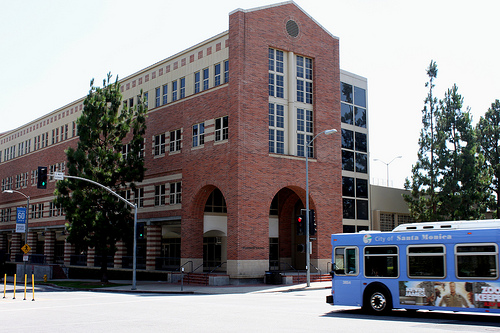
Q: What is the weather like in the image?
A: It is cloudy.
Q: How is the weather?
A: It is cloudy.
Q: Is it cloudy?
A: Yes, it is cloudy.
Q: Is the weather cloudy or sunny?
A: It is cloudy.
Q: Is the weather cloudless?
A: No, it is cloudy.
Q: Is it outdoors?
A: Yes, it is outdoors.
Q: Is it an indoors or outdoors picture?
A: It is outdoors.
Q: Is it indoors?
A: No, it is outdoors.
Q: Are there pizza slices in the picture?
A: No, there are no pizza slices.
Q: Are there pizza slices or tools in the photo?
A: No, there are no pizza slices or tools.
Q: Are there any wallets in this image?
A: No, there are no wallets.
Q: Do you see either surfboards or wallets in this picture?
A: No, there are no wallets or surfboards.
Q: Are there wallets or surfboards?
A: No, there are no wallets or surfboards.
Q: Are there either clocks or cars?
A: No, there are no cars or clocks.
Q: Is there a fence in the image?
A: No, there are no fences.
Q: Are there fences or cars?
A: No, there are no fences or cars.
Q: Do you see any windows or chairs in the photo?
A: Yes, there is a window.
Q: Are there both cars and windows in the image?
A: No, there is a window but no cars.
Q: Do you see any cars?
A: No, there are no cars.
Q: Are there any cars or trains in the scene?
A: No, there are no cars or trains.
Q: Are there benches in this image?
A: No, there are no benches.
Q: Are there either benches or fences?
A: No, there are no benches or fences.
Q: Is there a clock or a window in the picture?
A: Yes, there is a window.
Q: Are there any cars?
A: No, there are no cars.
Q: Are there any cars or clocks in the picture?
A: No, there are no cars or clocks.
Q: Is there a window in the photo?
A: Yes, there is a window.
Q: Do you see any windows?
A: Yes, there is a window.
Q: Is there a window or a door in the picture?
A: Yes, there is a window.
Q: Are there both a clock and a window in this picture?
A: No, there is a window but no clocks.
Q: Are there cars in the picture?
A: No, there are no cars.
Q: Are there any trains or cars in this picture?
A: No, there are no cars or trains.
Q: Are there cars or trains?
A: No, there are no cars or trains.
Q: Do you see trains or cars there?
A: No, there are no cars or trains.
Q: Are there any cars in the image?
A: No, there are no cars.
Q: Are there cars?
A: No, there are no cars.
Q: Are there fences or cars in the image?
A: No, there are no cars or fences.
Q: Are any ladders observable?
A: No, there are no ladders.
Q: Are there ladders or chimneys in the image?
A: No, there are no ladders or chimneys.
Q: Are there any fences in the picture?
A: No, there are no fences.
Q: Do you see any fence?
A: No, there are no fences.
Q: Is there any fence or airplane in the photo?
A: No, there are no fences or airplanes.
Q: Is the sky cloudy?
A: Yes, the sky is cloudy.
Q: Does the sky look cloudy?
A: Yes, the sky is cloudy.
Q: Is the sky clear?
A: No, the sky is cloudy.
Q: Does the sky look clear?
A: No, the sky is cloudy.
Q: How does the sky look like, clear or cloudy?
A: The sky is cloudy.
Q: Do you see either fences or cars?
A: No, there are no cars or fences.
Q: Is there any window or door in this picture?
A: Yes, there is a window.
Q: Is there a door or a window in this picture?
A: Yes, there is a window.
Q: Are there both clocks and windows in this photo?
A: No, there is a window but no clocks.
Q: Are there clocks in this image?
A: No, there are no clocks.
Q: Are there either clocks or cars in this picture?
A: No, there are no clocks or cars.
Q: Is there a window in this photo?
A: Yes, there is a window.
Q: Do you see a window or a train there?
A: Yes, there is a window.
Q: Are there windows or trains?
A: Yes, there is a window.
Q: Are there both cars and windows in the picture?
A: No, there is a window but no cars.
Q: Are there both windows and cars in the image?
A: No, there is a window but no cars.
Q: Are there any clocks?
A: No, there are no clocks.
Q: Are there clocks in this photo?
A: No, there are no clocks.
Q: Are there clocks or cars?
A: No, there are no clocks or cars.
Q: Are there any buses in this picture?
A: Yes, there is a bus.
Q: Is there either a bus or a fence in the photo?
A: Yes, there is a bus.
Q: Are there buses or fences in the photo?
A: Yes, there is a bus.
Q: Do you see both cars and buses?
A: No, there is a bus but no cars.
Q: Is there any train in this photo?
A: No, there are no trains.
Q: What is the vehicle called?
A: The vehicle is a bus.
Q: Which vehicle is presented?
A: The vehicle is a bus.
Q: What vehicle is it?
A: The vehicle is a bus.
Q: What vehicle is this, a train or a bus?
A: This is a bus.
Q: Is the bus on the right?
A: Yes, the bus is on the right of the image.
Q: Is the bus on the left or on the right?
A: The bus is on the right of the image.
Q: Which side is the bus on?
A: The bus is on the right of the image.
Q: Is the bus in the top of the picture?
A: No, the bus is in the bottom of the image.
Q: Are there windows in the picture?
A: Yes, there is a window.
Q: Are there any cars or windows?
A: Yes, there is a window.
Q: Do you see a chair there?
A: No, there are no chairs.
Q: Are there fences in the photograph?
A: No, there are no fences.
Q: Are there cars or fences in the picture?
A: No, there are no fences or cars.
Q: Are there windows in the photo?
A: Yes, there is a window.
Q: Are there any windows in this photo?
A: Yes, there is a window.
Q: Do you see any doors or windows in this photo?
A: Yes, there is a window.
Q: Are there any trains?
A: No, there are no trains.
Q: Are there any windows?
A: Yes, there is a window.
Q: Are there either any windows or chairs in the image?
A: Yes, there is a window.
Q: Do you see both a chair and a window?
A: No, there is a window but no chairs.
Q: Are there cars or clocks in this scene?
A: No, there are no cars or clocks.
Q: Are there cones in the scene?
A: No, there are no cones.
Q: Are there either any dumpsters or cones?
A: No, there are no cones or dumpsters.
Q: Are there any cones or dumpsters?
A: No, there are no cones or dumpsters.